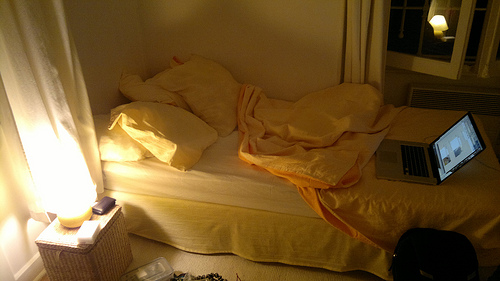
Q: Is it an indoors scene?
A: Yes, it is indoors.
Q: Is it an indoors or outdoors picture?
A: It is indoors.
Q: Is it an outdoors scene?
A: No, it is indoors.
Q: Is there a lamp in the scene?
A: Yes, there is a lamp.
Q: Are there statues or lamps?
A: Yes, there is a lamp.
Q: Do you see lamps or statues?
A: Yes, there is a lamp.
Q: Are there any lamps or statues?
A: Yes, there is a lamp.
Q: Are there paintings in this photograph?
A: No, there are no paintings.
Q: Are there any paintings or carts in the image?
A: No, there are no paintings or carts.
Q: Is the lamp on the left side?
A: Yes, the lamp is on the left of the image.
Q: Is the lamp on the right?
A: No, the lamp is on the left of the image.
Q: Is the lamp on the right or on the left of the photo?
A: The lamp is on the left of the image.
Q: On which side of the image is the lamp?
A: The lamp is on the left of the image.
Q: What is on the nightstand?
A: The lamp is on the nightstand.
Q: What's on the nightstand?
A: The lamp is on the nightstand.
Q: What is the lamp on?
A: The lamp is on the nightstand.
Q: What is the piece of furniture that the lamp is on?
A: The piece of furniture is a nightstand.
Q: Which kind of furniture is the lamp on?
A: The lamp is on the nightstand.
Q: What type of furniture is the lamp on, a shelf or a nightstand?
A: The lamp is on a nightstand.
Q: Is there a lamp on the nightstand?
A: Yes, there is a lamp on the nightstand.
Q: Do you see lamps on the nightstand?
A: Yes, there is a lamp on the nightstand.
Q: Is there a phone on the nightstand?
A: No, there is a lamp on the nightstand.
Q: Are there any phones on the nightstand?
A: No, there is a lamp on the nightstand.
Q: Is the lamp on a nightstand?
A: Yes, the lamp is on a nightstand.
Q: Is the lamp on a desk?
A: No, the lamp is on a nightstand.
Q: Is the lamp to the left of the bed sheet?
A: Yes, the lamp is to the left of the bed sheet.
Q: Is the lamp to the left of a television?
A: No, the lamp is to the left of the bed sheet.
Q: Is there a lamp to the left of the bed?
A: Yes, there is a lamp to the left of the bed.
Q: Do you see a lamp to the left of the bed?
A: Yes, there is a lamp to the left of the bed.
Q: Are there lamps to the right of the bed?
A: No, the lamp is to the left of the bed.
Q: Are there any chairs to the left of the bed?
A: No, there is a lamp to the left of the bed.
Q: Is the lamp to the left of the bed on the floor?
A: Yes, the lamp is to the left of the bed.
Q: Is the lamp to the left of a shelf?
A: No, the lamp is to the left of the bed.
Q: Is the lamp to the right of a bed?
A: No, the lamp is to the left of a bed.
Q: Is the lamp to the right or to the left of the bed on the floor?
A: The lamp is to the left of the bed.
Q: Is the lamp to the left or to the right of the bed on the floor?
A: The lamp is to the left of the bed.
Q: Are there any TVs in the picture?
A: No, there are no tvs.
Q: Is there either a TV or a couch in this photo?
A: No, there are no televisions or couches.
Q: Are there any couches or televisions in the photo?
A: No, there are no televisions or couches.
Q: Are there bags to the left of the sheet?
A: No, there is a curtain to the left of the sheet.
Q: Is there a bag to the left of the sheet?
A: No, there is a curtain to the left of the sheet.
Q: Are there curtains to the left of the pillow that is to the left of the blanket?
A: Yes, there is a curtain to the left of the pillow.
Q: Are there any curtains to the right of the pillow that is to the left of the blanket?
A: No, the curtain is to the left of the pillow.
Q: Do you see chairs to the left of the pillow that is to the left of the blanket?
A: No, there is a curtain to the left of the pillow.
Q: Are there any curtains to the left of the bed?
A: Yes, there is a curtain to the left of the bed.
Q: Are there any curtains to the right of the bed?
A: No, the curtain is to the left of the bed.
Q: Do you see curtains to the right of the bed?
A: No, the curtain is to the left of the bed.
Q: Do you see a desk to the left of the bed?
A: No, there is a curtain to the left of the bed.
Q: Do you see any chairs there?
A: No, there are no chairs.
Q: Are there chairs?
A: No, there are no chairs.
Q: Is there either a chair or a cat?
A: No, there are no chairs or cats.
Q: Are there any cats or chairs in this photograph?
A: No, there are no chairs or cats.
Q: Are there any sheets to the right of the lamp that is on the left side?
A: Yes, there is a sheet to the right of the lamp.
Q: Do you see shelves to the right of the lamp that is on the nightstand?
A: No, there is a sheet to the right of the lamp.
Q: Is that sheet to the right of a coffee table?
A: No, the sheet is to the right of a lamp.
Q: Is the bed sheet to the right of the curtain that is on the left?
A: Yes, the bed sheet is to the right of the curtain.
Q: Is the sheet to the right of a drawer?
A: No, the sheet is to the right of the curtain.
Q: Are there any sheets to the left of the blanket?
A: Yes, there is a sheet to the left of the blanket.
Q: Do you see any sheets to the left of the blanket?
A: Yes, there is a sheet to the left of the blanket.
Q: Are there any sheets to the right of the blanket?
A: No, the sheet is to the left of the blanket.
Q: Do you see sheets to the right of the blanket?
A: No, the sheet is to the left of the blanket.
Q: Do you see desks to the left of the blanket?
A: No, there is a sheet to the left of the blanket.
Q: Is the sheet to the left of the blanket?
A: Yes, the sheet is to the left of the blanket.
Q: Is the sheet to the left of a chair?
A: No, the sheet is to the left of the blanket.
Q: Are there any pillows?
A: Yes, there is a pillow.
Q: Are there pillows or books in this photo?
A: Yes, there is a pillow.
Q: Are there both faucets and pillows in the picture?
A: No, there is a pillow but no faucets.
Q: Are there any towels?
A: No, there are no towels.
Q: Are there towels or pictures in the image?
A: No, there are no towels or pictures.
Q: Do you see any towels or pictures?
A: No, there are no towels or pictures.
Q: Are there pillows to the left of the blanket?
A: Yes, there is a pillow to the left of the blanket.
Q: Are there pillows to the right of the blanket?
A: No, the pillow is to the left of the blanket.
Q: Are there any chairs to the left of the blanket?
A: No, there is a pillow to the left of the blanket.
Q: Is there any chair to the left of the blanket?
A: No, there is a pillow to the left of the blanket.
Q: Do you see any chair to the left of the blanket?
A: No, there is a pillow to the left of the blanket.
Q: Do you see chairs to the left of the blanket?
A: No, there is a pillow to the left of the blanket.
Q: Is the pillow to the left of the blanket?
A: Yes, the pillow is to the left of the blanket.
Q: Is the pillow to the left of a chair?
A: No, the pillow is to the left of the blanket.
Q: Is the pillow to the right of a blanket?
A: No, the pillow is to the left of a blanket.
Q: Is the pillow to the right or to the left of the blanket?
A: The pillow is to the left of the blanket.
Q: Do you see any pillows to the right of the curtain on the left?
A: Yes, there is a pillow to the right of the curtain.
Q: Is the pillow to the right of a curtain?
A: Yes, the pillow is to the right of a curtain.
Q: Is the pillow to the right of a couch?
A: No, the pillow is to the right of a curtain.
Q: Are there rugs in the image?
A: No, there are no rugs.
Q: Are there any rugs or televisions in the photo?
A: No, there are no rugs or televisions.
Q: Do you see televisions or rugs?
A: No, there are no rugs or televisions.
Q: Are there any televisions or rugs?
A: No, there are no rugs or televisions.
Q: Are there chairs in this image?
A: No, there are no chairs.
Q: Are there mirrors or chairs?
A: No, there are no chairs or mirrors.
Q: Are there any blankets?
A: Yes, there is a blanket.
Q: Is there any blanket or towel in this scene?
A: Yes, there is a blanket.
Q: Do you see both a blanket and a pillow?
A: Yes, there are both a blanket and a pillow.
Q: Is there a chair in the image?
A: No, there are no chairs.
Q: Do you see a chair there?
A: No, there are no chairs.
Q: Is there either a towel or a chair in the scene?
A: No, there are no chairs or towels.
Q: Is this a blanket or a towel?
A: This is a blanket.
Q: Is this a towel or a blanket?
A: This is a blanket.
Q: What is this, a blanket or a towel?
A: This is a blanket.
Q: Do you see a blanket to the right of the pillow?
A: Yes, there is a blanket to the right of the pillow.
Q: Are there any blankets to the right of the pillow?
A: Yes, there is a blanket to the right of the pillow.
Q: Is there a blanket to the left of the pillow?
A: No, the blanket is to the right of the pillow.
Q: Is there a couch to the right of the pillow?
A: No, there is a blanket to the right of the pillow.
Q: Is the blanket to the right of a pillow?
A: Yes, the blanket is to the right of a pillow.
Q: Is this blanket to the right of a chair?
A: No, the blanket is to the right of a pillow.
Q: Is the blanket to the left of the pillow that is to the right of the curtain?
A: No, the blanket is to the right of the pillow.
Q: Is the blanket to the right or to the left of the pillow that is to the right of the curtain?
A: The blanket is to the right of the pillow.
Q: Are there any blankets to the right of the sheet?
A: Yes, there is a blanket to the right of the sheet.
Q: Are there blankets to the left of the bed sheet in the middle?
A: No, the blanket is to the right of the bed sheet.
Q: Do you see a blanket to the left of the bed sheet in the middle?
A: No, the blanket is to the right of the bed sheet.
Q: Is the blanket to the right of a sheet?
A: Yes, the blanket is to the right of a sheet.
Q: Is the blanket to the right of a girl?
A: No, the blanket is to the right of a sheet.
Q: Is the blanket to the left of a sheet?
A: No, the blanket is to the right of a sheet.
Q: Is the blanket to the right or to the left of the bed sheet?
A: The blanket is to the right of the bed sheet.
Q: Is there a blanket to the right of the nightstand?
A: Yes, there is a blanket to the right of the nightstand.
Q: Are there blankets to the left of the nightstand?
A: No, the blanket is to the right of the nightstand.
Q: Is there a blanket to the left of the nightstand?
A: No, the blanket is to the right of the nightstand.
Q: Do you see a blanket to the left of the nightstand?
A: No, the blanket is to the right of the nightstand.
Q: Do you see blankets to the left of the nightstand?
A: No, the blanket is to the right of the nightstand.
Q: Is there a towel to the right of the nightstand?
A: No, there is a blanket to the right of the nightstand.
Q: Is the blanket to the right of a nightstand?
A: Yes, the blanket is to the right of a nightstand.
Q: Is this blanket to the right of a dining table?
A: No, the blanket is to the right of a nightstand.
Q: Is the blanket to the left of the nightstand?
A: No, the blanket is to the right of the nightstand.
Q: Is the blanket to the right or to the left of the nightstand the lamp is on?
A: The blanket is to the right of the nightstand.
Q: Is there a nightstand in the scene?
A: Yes, there is a nightstand.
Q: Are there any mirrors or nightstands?
A: Yes, there is a nightstand.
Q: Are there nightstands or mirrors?
A: Yes, there is a nightstand.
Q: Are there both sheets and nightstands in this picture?
A: Yes, there are both a nightstand and a sheet.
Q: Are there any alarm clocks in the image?
A: No, there are no alarm clocks.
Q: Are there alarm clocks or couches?
A: No, there are no alarm clocks or couches.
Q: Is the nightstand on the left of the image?
A: Yes, the nightstand is on the left of the image.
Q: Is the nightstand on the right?
A: No, the nightstand is on the left of the image.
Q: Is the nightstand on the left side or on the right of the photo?
A: The nightstand is on the left of the image.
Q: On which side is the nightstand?
A: The nightstand is on the left of the image.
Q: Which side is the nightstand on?
A: The nightstand is on the left of the image.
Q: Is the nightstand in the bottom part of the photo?
A: Yes, the nightstand is in the bottom of the image.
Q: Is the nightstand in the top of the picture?
A: No, the nightstand is in the bottom of the image.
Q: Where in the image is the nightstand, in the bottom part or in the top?
A: The nightstand is in the bottom of the image.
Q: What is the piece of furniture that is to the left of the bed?
A: The piece of furniture is a nightstand.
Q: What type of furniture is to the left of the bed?
A: The piece of furniture is a nightstand.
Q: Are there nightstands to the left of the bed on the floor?
A: Yes, there is a nightstand to the left of the bed.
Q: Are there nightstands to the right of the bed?
A: No, the nightstand is to the left of the bed.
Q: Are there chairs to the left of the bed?
A: No, there is a nightstand to the left of the bed.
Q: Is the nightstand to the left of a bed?
A: Yes, the nightstand is to the left of a bed.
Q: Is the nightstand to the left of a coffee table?
A: No, the nightstand is to the left of a bed.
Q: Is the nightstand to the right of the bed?
A: No, the nightstand is to the left of the bed.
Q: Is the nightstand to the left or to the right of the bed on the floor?
A: The nightstand is to the left of the bed.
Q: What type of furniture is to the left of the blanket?
A: The piece of furniture is a nightstand.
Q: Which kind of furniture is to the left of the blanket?
A: The piece of furniture is a nightstand.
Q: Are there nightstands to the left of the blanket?
A: Yes, there is a nightstand to the left of the blanket.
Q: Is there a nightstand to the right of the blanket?
A: No, the nightstand is to the left of the blanket.